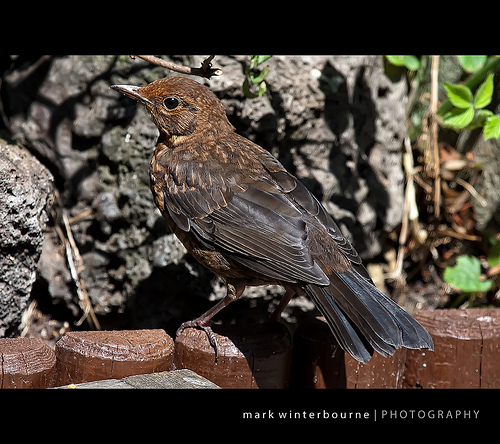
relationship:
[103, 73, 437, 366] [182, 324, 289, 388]
bird on pole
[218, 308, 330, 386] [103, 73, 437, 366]
shade belongs to bird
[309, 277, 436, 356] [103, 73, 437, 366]
tail belongs to bird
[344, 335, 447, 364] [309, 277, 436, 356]
feather on tail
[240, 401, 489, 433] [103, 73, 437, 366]
graphic below bird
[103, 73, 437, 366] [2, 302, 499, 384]
bird on poles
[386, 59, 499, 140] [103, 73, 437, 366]
leaves to right of bird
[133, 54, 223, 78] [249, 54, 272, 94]
branch near leaf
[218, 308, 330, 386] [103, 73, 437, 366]
shade cast by bird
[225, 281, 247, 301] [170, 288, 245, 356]
knee on leg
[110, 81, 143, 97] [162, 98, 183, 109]
beak near eye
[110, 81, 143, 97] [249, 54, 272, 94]
beak near leaf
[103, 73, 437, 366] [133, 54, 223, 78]
bird below branch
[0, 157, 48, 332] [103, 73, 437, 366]
rocks to left of bird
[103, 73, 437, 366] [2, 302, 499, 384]
bird on brown poles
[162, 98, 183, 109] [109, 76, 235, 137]
eye on head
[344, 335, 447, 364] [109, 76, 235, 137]
feather below head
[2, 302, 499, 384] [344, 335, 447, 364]
poles below feather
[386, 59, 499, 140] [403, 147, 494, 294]
leaves on bush